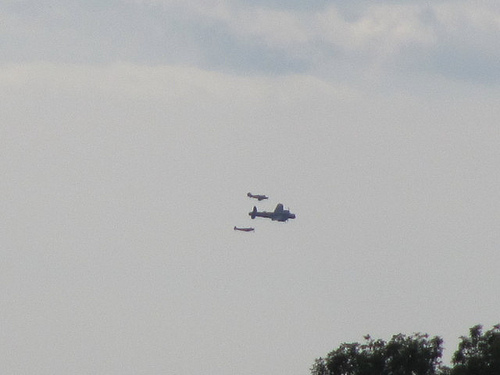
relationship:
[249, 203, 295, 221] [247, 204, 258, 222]
airplanes has tail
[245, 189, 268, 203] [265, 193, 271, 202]
plane has propellers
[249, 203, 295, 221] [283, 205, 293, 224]
airplanes has propellers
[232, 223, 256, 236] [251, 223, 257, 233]
plane has propellers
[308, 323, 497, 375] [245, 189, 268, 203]
trees below plane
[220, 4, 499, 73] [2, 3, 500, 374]
clouds in sky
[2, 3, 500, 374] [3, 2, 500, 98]
sky has patches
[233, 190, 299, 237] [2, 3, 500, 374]
airplanes in sky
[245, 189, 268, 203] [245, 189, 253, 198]
plane has tail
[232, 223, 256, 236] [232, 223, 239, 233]
plane has tail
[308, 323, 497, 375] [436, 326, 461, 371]
trees have gap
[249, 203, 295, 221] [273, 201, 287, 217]
airplanes has wing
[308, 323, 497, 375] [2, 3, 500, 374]
trees under sky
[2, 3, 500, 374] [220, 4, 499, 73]
sky has clouds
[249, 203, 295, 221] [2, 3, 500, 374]
airplanes in sky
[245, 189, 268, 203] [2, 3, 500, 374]
plane in sky